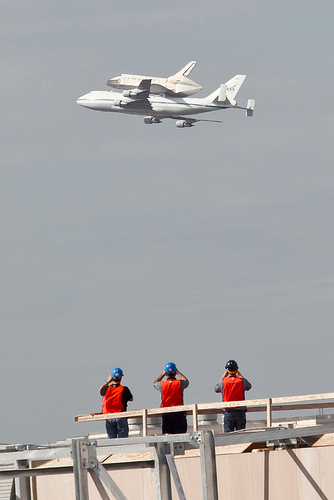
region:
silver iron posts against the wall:
[50, 424, 278, 474]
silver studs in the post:
[181, 425, 205, 449]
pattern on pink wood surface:
[104, 448, 156, 463]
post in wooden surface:
[136, 402, 152, 440]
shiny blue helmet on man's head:
[107, 357, 127, 378]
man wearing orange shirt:
[153, 377, 190, 402]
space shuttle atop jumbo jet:
[103, 61, 204, 91]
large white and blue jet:
[57, 82, 265, 134]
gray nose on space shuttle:
[96, 77, 126, 88]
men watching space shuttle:
[72, 356, 272, 435]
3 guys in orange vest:
[100, 341, 267, 493]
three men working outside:
[90, 358, 253, 447]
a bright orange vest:
[101, 381, 132, 421]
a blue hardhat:
[156, 358, 183, 378]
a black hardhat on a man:
[213, 353, 242, 378]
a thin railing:
[70, 386, 332, 427]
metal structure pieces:
[38, 430, 233, 498]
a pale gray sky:
[58, 221, 230, 314]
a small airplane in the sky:
[91, 46, 204, 101]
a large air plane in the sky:
[66, 73, 265, 125]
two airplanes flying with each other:
[60, 38, 261, 145]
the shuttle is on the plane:
[69, 60, 258, 135]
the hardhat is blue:
[109, 363, 125, 375]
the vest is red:
[158, 378, 187, 405]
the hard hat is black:
[222, 354, 244, 373]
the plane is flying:
[72, 87, 269, 123]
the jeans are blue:
[99, 420, 132, 438]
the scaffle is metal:
[64, 438, 105, 483]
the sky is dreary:
[29, 170, 296, 299]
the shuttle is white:
[95, 56, 204, 91]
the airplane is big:
[64, 81, 263, 132]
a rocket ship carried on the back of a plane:
[69, 58, 259, 135]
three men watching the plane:
[79, 368, 268, 424]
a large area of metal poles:
[23, 434, 289, 494]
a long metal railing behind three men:
[81, 396, 331, 426]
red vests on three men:
[102, 383, 247, 407]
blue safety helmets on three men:
[108, 365, 245, 382]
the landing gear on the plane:
[136, 108, 198, 132]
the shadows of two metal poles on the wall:
[255, 453, 332, 498]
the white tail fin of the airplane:
[214, 70, 253, 100]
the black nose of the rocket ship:
[107, 77, 119, 88]